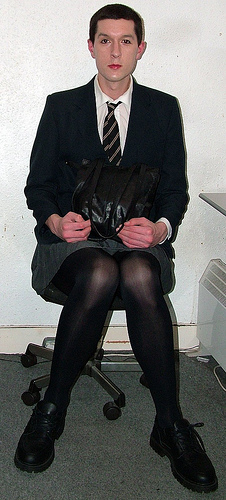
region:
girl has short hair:
[82, 8, 160, 43]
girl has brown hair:
[88, 8, 154, 43]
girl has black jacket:
[38, 75, 204, 233]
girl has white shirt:
[86, 79, 132, 171]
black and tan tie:
[88, 84, 134, 171]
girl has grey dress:
[7, 228, 203, 305]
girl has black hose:
[39, 231, 172, 420]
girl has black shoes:
[142, 384, 216, 485]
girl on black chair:
[16, 275, 170, 425]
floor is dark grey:
[85, 434, 131, 496]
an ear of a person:
[86, 37, 95, 60]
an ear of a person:
[135, 38, 148, 62]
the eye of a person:
[98, 37, 113, 46]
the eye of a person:
[120, 36, 133, 47]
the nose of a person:
[110, 37, 122, 58]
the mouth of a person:
[103, 61, 123, 71]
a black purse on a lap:
[62, 156, 164, 246]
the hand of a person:
[114, 215, 158, 249]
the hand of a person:
[56, 208, 90, 244]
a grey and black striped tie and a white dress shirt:
[88, 86, 139, 174]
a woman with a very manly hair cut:
[74, 3, 157, 83]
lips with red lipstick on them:
[102, 55, 128, 77]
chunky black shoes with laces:
[142, 405, 218, 494]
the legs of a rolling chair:
[20, 319, 174, 417]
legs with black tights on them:
[32, 248, 203, 407]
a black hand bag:
[64, 151, 176, 257]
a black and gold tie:
[93, 87, 127, 158]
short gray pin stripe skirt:
[27, 232, 194, 284]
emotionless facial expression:
[96, 29, 134, 71]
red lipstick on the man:
[107, 62, 123, 69]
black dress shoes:
[15, 401, 220, 494]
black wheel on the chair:
[102, 398, 125, 419]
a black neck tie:
[103, 101, 125, 164]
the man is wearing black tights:
[46, 251, 181, 411]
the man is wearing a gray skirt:
[33, 231, 173, 295]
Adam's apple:
[108, 81, 120, 95]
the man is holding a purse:
[53, 155, 167, 251]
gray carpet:
[0, 354, 223, 498]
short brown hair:
[88, 3, 143, 47]